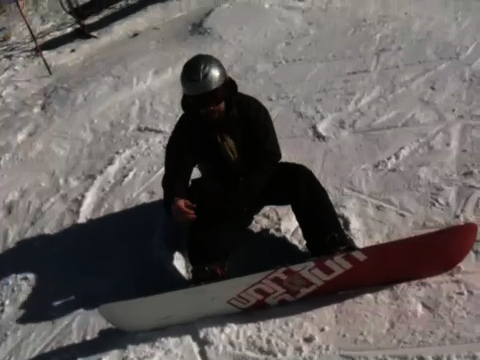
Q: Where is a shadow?
A: On the snow.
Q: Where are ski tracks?
A: On the snow.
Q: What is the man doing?
A: Snowboarding.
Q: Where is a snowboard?
A: Under man's feet.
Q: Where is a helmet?
A: On man's head.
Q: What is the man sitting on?
A: Snow.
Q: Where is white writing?
A: On snowboard.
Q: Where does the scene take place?
A: On a ski slope.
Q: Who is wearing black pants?
A: Snowboarder.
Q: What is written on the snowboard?
A: Unity.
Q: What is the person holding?
A: Snowboard.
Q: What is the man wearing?
A: Coat.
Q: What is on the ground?
A: Snow.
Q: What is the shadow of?
A: Man's reflection.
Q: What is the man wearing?
A: Ski pants.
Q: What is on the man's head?
A: Helmet.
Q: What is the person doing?
A: Snowboarding.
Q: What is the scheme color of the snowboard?
A: Red and white.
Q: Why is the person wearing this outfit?
A: For protection.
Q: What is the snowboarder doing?
A: Sitting.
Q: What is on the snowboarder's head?
A: Helmet.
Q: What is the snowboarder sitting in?
A: Snow.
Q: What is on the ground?
A: Snow.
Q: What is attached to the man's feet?
A: Snowboard.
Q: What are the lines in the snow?
A: Tracks.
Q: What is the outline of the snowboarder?
A: Shadow.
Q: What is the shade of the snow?
A: White.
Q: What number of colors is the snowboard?
A: 2.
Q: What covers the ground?
A: Snow.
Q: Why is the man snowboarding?
A: There is snow.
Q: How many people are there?
A: One.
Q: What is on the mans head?
A: A helmet.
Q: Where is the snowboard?
A: On the ground.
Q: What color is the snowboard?
A: Red and white.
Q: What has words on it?
A: The snowboard.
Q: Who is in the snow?
A: The snowboarder.